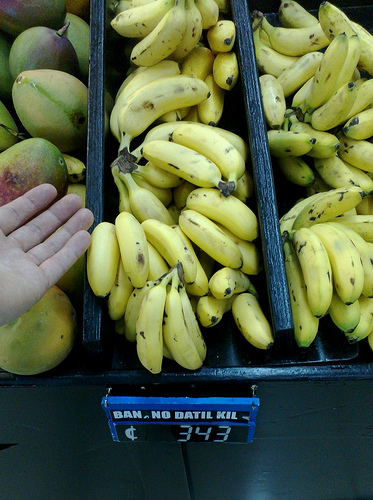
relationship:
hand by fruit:
[0, 182, 96, 329] [1, 137, 69, 237]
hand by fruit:
[0, 182, 96, 329] [66, 183, 87, 210]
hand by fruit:
[0, 182, 96, 329] [55, 250, 87, 296]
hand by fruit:
[0, 182, 96, 329] [1, 284, 77, 375]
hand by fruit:
[0, 182, 96, 329] [84, 221, 121, 299]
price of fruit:
[177, 424, 232, 444] [1, 284, 77, 375]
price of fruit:
[177, 424, 232, 444] [55, 250, 87, 296]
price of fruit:
[177, 424, 232, 444] [84, 221, 121, 299]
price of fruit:
[177, 424, 232, 444] [66, 183, 87, 210]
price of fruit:
[177, 424, 232, 444] [1, 137, 69, 237]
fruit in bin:
[84, 221, 121, 299] [84, 0, 294, 375]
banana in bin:
[180, 188, 257, 243] [84, 0, 294, 375]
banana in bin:
[168, 123, 245, 191] [84, 0, 294, 375]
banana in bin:
[205, 19, 236, 53] [84, 0, 294, 375]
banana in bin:
[118, 74, 212, 158] [84, 0, 294, 375]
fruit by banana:
[1, 137, 69, 237] [118, 74, 212, 158]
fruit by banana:
[66, 183, 87, 210] [180, 188, 257, 243]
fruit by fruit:
[55, 250, 87, 296] [84, 221, 121, 299]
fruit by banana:
[1, 284, 77, 375] [180, 188, 257, 243]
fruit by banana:
[12, 69, 88, 155] [129, 0, 187, 67]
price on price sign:
[177, 424, 232, 444] [100, 384, 260, 446]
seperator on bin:
[80, 0, 105, 344] [84, 0, 294, 375]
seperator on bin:
[80, 0, 105, 344] [0, 1, 125, 376]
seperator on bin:
[229, 0, 294, 338] [229, 0, 372, 368]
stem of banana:
[227, 173, 239, 193] [168, 123, 245, 191]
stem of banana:
[116, 130, 134, 155] [118, 74, 212, 158]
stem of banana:
[175, 1, 185, 13] [129, 0, 187, 67]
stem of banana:
[160, 267, 180, 286] [134, 264, 179, 376]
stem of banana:
[170, 267, 182, 293] [162, 267, 204, 372]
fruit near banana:
[12, 69, 88, 155] [118, 74, 212, 158]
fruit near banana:
[1, 137, 69, 237] [168, 123, 245, 191]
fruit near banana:
[66, 183, 87, 210] [180, 188, 257, 243]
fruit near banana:
[55, 250, 87, 296] [134, 264, 179, 376]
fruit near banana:
[1, 284, 77, 375] [162, 267, 204, 372]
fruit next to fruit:
[1, 137, 69, 237] [66, 183, 87, 210]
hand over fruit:
[0, 182, 96, 329] [66, 183, 87, 210]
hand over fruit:
[0, 182, 96, 329] [1, 137, 69, 237]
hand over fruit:
[0, 182, 96, 329] [55, 250, 87, 296]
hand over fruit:
[0, 182, 96, 329] [1, 284, 77, 375]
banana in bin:
[129, 0, 187, 67] [84, 0, 294, 375]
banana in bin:
[162, 267, 204, 372] [84, 0, 294, 375]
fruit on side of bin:
[12, 69, 88, 155] [84, 0, 294, 375]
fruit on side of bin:
[1, 137, 69, 237] [84, 0, 294, 375]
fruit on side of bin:
[66, 183, 87, 210] [84, 0, 294, 375]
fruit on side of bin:
[55, 250, 87, 296] [84, 0, 294, 375]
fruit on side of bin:
[1, 284, 77, 375] [84, 0, 294, 375]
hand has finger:
[0, 182, 96, 329] [1, 181, 56, 236]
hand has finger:
[0, 182, 96, 329] [8, 192, 83, 252]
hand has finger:
[0, 182, 96, 329] [26, 207, 95, 265]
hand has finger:
[0, 182, 96, 329] [40, 228, 91, 286]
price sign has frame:
[100, 384, 260, 446] [99, 397, 260, 443]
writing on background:
[112, 410, 239, 421] [109, 409, 251, 423]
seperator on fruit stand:
[80, 0, 105, 344] [0, 0, 372, 500]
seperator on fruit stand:
[229, 0, 294, 338] [0, 0, 372, 500]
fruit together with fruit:
[12, 69, 88, 155] [1, 137, 69, 237]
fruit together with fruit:
[66, 183, 87, 210] [55, 250, 87, 296]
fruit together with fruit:
[55, 250, 87, 296] [1, 284, 77, 375]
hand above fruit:
[0, 182, 96, 329] [1, 137, 69, 237]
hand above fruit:
[0, 182, 96, 329] [66, 183, 87, 210]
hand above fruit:
[0, 182, 96, 329] [55, 250, 87, 296]